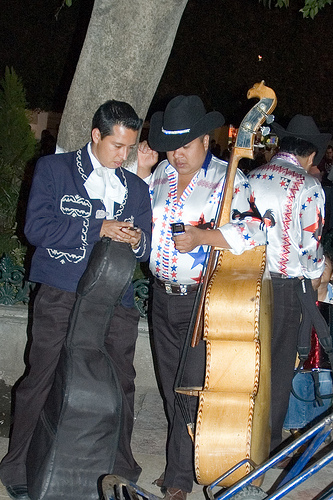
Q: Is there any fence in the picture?
A: No, there are no fences.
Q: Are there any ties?
A: Yes, there is a tie.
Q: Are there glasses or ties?
A: Yes, there is a tie.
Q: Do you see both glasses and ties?
A: No, there is a tie but no glasses.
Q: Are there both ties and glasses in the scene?
A: No, there is a tie but no glasses.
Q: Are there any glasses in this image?
A: No, there are no glasses.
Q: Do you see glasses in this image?
A: No, there are no glasses.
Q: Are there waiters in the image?
A: No, there are no waiters.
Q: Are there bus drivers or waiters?
A: No, there are no waiters or bus drivers.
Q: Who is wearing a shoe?
A: The man is wearing a shoe.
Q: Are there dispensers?
A: No, there are no dispensers.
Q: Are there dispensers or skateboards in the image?
A: No, there are no dispensers or skateboards.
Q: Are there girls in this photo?
A: No, there are no girls.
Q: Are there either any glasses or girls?
A: No, there are no girls or glasses.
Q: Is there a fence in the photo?
A: No, there are no fences.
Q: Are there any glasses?
A: No, there are no glasses.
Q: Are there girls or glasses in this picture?
A: No, there are no glasses or girls.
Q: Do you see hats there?
A: Yes, there is a hat.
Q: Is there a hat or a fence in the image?
A: Yes, there is a hat.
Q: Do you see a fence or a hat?
A: Yes, there is a hat.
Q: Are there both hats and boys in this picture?
A: No, there is a hat but no boys.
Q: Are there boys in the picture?
A: No, there are no boys.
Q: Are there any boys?
A: No, there are no boys.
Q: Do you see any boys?
A: No, there are no boys.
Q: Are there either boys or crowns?
A: No, there are no boys or crowns.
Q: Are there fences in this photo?
A: No, there are no fences.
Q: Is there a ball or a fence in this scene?
A: No, there are no fences or balls.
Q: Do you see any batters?
A: No, there are no batters.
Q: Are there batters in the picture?
A: No, there are no batters.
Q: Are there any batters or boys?
A: No, there are no batters or boys.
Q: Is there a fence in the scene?
A: No, there are no fences.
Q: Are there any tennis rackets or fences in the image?
A: No, there are no fences or tennis rackets.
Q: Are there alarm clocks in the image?
A: No, there are no alarm clocks.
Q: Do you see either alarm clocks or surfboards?
A: No, there are no alarm clocks or surfboards.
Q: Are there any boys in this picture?
A: No, there are no boys.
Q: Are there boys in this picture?
A: No, there are no boys.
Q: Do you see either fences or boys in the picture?
A: No, there are no boys or fences.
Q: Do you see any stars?
A: Yes, there is a star.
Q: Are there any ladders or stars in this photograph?
A: Yes, there is a star.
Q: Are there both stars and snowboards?
A: No, there is a star but no snowboards.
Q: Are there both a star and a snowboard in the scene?
A: No, there is a star but no snowboards.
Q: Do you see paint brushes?
A: No, there are no paint brushes.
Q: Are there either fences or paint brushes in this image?
A: No, there are no paint brushes or fences.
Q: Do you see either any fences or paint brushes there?
A: No, there are no paint brushes or fences.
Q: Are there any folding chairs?
A: No, there are no folding chairs.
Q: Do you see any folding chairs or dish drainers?
A: No, there are no folding chairs or dish drainers.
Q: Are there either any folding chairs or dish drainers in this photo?
A: No, there are no folding chairs or dish drainers.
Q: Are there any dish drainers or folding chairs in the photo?
A: No, there are no folding chairs or dish drainers.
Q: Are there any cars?
A: No, there are no cars.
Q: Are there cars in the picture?
A: No, there are no cars.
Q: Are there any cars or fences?
A: No, there are no cars or fences.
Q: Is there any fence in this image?
A: No, there are no fences.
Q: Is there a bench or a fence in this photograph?
A: No, there are no fences or benches.